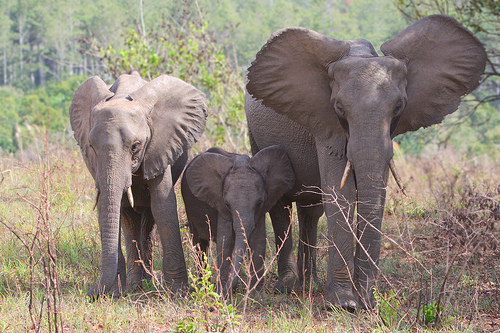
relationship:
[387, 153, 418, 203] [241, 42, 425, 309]
tusk of elephant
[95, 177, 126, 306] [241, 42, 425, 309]
trunk of elephant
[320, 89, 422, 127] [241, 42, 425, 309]
eyes of elephant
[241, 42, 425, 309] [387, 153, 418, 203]
elephant has tusk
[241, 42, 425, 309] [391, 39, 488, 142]
elephant has big ears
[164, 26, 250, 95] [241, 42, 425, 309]
bushes behind elephant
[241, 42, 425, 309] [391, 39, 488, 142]
elephant with big ears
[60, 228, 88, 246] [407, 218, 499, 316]
grass in field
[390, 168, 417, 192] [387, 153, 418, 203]
mud on tusk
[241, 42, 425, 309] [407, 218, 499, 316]
elephant in field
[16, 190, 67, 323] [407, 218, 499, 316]
sticks in field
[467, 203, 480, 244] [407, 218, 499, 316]
weeds on field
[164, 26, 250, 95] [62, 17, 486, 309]
bushes behind elephants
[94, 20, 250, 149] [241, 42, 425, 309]
bushes behind elephant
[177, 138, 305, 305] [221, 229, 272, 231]
baby elephant has small tusks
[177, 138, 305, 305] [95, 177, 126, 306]
baby elephant has trunk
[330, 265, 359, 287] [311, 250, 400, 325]
wrinkles on feet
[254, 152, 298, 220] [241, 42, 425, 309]
ear of elephant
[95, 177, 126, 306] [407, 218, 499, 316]
trunk on field